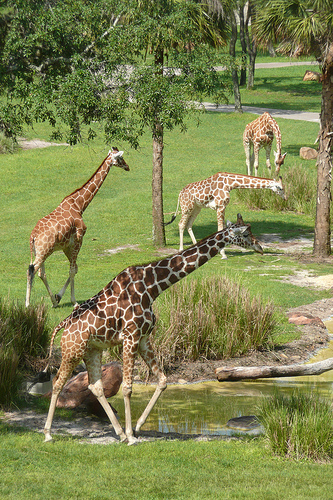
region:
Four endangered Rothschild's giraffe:
[26, 111, 288, 446]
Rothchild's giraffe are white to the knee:
[44, 381, 170, 444]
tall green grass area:
[257, 388, 332, 457]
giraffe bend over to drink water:
[170, 111, 309, 249]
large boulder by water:
[59, 363, 122, 405]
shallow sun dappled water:
[113, 380, 331, 438]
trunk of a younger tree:
[145, 73, 167, 256]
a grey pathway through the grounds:
[95, 43, 322, 126]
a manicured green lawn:
[2, 37, 301, 268]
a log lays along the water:
[216, 358, 332, 389]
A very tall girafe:
[25, 146, 130, 305]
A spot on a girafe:
[152, 265, 171, 282]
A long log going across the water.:
[215, 355, 332, 382]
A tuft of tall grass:
[249, 381, 332, 462]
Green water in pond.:
[0, 317, 332, 434]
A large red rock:
[38, 360, 123, 407]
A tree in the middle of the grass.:
[0, 0, 250, 247]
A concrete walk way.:
[0, 60, 321, 122]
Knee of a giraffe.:
[120, 384, 131, 396]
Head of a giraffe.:
[225, 211, 263, 254]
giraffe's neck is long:
[139, 220, 234, 298]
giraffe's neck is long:
[71, 151, 123, 209]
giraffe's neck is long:
[223, 165, 277, 217]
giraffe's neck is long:
[273, 135, 291, 159]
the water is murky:
[174, 379, 191, 410]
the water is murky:
[200, 399, 240, 423]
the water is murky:
[138, 386, 197, 434]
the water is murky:
[217, 382, 274, 408]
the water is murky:
[303, 347, 318, 391]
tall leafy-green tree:
[3, 0, 231, 252]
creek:
[0, 373, 332, 442]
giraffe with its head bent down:
[235, 105, 287, 176]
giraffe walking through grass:
[18, 140, 131, 318]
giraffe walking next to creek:
[32, 209, 263, 449]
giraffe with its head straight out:
[152, 168, 285, 266]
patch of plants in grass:
[255, 384, 330, 461]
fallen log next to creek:
[208, 347, 329, 379]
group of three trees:
[213, 0, 271, 123]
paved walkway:
[104, 87, 320, 125]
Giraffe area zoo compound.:
[22, 86, 313, 458]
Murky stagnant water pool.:
[109, 371, 331, 441]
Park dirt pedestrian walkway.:
[124, 85, 328, 125]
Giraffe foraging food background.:
[236, 108, 307, 184]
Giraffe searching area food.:
[170, 163, 300, 226]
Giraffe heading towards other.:
[8, 136, 136, 301]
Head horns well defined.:
[105, 140, 132, 179]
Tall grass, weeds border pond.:
[156, 394, 331, 496]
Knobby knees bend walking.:
[46, 313, 178, 447]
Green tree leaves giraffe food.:
[11, 5, 195, 234]